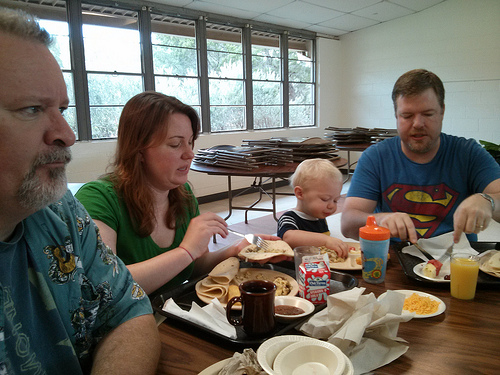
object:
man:
[340, 67, 500, 240]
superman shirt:
[346, 134, 500, 243]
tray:
[152, 258, 358, 346]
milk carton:
[297, 253, 331, 301]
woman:
[76, 92, 282, 301]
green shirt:
[75, 169, 206, 295]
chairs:
[194, 134, 340, 170]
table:
[187, 153, 345, 178]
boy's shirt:
[277, 210, 331, 243]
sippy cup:
[357, 215, 391, 283]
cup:
[450, 252, 478, 299]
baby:
[277, 157, 349, 260]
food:
[317, 244, 370, 267]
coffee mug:
[225, 279, 280, 336]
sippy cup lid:
[358, 216, 388, 238]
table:
[98, 239, 500, 375]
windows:
[9, 7, 316, 142]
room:
[1, 0, 500, 375]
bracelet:
[175, 245, 197, 261]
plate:
[254, 333, 352, 375]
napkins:
[309, 286, 412, 374]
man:
[1, 6, 159, 375]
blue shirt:
[0, 185, 152, 373]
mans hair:
[1, 10, 65, 45]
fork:
[219, 226, 271, 249]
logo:
[381, 183, 461, 240]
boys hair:
[291, 157, 344, 185]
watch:
[477, 192, 500, 204]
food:
[412, 242, 474, 279]